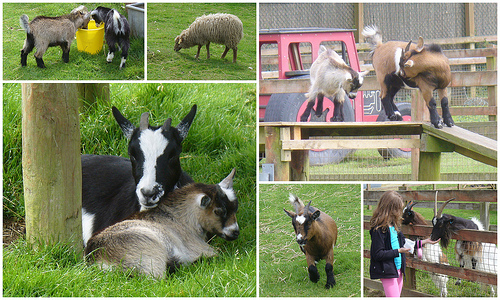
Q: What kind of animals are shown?
A: Goats and a sheep.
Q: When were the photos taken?
A: Daytime.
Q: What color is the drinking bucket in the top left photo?
A: Yellow.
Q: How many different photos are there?
A: Six.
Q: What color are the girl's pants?
A: Pink.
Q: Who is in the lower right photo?
A: A girl.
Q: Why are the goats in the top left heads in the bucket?
A: To drink water.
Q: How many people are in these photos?
A: One.